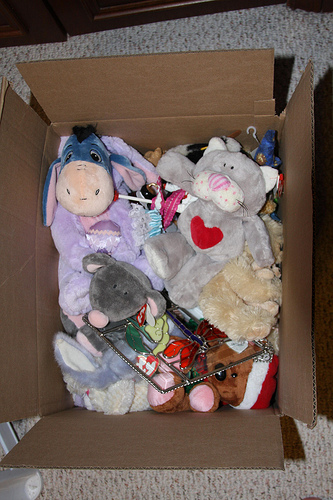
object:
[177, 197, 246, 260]
belly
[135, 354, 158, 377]
label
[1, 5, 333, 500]
carpet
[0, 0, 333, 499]
floor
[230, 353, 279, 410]
hat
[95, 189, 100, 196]
nose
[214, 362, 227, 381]
nose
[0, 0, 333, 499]
ground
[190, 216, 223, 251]
heart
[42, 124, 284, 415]
animal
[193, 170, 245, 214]
polka dots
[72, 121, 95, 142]
hair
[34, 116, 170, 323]
eyore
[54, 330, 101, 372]
ear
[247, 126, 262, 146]
hook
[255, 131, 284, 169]
toy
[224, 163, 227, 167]
eye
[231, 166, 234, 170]
eye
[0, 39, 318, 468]
edge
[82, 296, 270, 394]
frame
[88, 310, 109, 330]
nose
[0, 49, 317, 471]
box